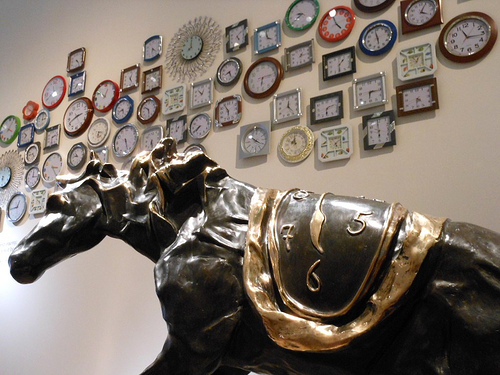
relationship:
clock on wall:
[350, 13, 405, 59] [7, 5, 474, 211]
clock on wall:
[435, 6, 497, 68] [265, 1, 475, 209]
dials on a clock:
[64, 108, 89, 128] [50, 92, 98, 136]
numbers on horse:
[270, 193, 392, 313] [8, 127, 494, 372]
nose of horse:
[3, 241, 54, 291] [8, 127, 494, 372]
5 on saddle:
[341, 203, 381, 248] [225, 176, 445, 367]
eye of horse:
[45, 188, 71, 217] [8, 127, 494, 372]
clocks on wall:
[0, 7, 498, 235] [4, 5, 489, 373]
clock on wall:
[243, 56, 290, 98] [4, 5, 489, 373]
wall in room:
[9, 48, 494, 370] [18, 9, 471, 359]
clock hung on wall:
[356, 105, 406, 156] [4, 5, 489, 373]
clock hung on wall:
[356, 16, 398, 55] [4, 5, 489, 373]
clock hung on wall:
[313, 2, 372, 53] [4, 5, 489, 373]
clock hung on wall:
[282, 2, 332, 37] [4, 5, 489, 373]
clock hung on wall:
[14, 88, 53, 131] [4, 5, 489, 373]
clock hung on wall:
[160, 11, 229, 82] [4, 5, 489, 373]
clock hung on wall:
[182, 108, 220, 148] [4, 5, 489, 373]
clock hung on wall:
[111, 122, 141, 163] [4, 5, 489, 373]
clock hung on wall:
[435, 6, 497, 68] [4, 5, 489, 373]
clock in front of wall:
[356, 16, 398, 55] [4, 5, 489, 373]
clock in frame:
[28, 73, 75, 114] [38, 71, 82, 120]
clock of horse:
[356, 16, 398, 55] [8, 127, 494, 372]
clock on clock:
[241, 176, 447, 356] [356, 16, 398, 55]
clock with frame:
[435, 6, 497, 68] [434, 10, 497, 70]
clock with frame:
[0, 110, 22, 147] [1, 112, 24, 147]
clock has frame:
[85, 74, 122, 119] [83, 77, 123, 115]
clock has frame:
[104, 87, 139, 131] [105, 95, 139, 126]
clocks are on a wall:
[0, 7, 498, 235] [4, 5, 489, 373]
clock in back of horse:
[2, 0, 494, 271] [8, 127, 494, 372]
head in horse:
[10, 161, 119, 283] [8, 127, 494, 372]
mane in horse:
[94, 160, 152, 210] [8, 127, 494, 372]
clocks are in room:
[0, 7, 498, 235] [3, 0, 493, 373]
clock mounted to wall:
[435, 6, 497, 68] [4, 5, 489, 373]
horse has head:
[8, 127, 494, 372] [10, 161, 119, 283]